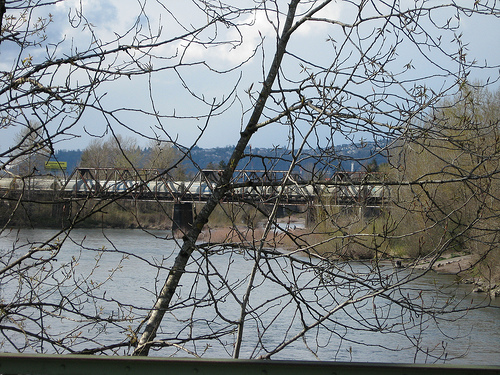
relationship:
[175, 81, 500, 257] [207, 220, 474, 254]
bush on river bank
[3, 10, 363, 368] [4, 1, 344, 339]
tree has no leaves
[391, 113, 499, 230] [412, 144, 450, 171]
brown leaves has brown leaves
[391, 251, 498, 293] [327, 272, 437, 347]
beach area on side of water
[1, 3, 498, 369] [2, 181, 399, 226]
river scene with bridge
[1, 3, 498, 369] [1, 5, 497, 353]
river scene with trees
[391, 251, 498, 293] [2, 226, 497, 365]
beach area on river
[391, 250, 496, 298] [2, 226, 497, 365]
rocks on side river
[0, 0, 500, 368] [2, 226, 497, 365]
branch with river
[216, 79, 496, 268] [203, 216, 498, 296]
bush on river bank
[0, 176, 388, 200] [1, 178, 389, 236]
train on bridge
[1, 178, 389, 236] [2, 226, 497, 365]
bridge crossing river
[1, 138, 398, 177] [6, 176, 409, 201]
hill in train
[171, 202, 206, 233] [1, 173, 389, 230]
bridge support for bridge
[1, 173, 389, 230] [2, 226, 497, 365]
bridge in river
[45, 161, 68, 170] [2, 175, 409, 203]
billboard behind train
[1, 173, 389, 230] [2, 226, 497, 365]
bridge cross river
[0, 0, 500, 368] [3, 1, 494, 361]
branch of tree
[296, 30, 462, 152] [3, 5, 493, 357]
leaves on branch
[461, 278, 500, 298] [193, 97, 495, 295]
rocks on river bank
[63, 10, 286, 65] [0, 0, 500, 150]
clouds in clear sky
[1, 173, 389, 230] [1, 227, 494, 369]
bridge over water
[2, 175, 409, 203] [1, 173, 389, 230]
train on bridge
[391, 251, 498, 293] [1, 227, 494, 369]
beach area next to water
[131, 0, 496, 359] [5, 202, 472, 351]
tree in front of the water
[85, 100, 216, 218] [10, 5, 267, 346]
branch on the tree